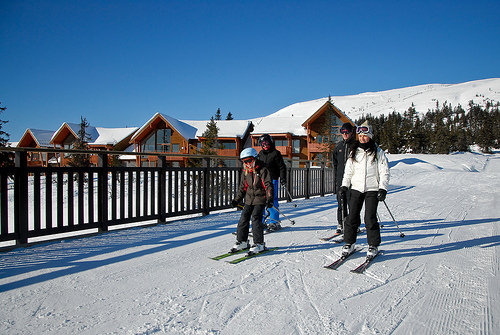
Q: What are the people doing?
A: Skiing.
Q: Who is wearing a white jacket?
A: The woman is.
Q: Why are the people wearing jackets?
A: Cold.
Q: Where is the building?
A: Behind the people.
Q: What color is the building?
A: Brown.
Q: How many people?
A: Four.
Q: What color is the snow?
A: White.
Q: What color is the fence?
A: Black.